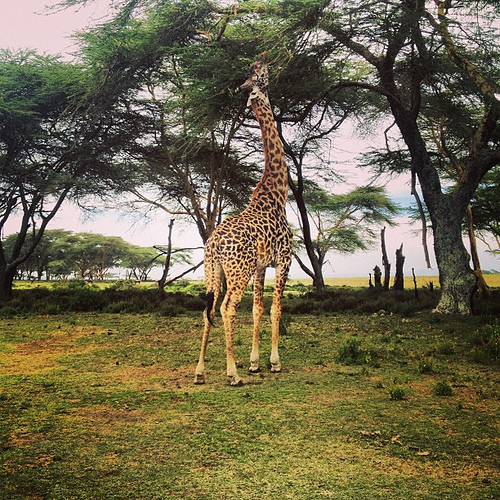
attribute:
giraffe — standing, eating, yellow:
[183, 81, 330, 395]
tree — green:
[4, 50, 147, 310]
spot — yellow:
[256, 228, 277, 242]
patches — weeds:
[335, 334, 380, 374]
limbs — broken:
[300, 64, 399, 130]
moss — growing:
[435, 247, 474, 301]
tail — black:
[193, 264, 227, 334]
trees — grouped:
[269, 30, 492, 315]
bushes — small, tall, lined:
[8, 279, 208, 324]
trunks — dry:
[350, 236, 415, 303]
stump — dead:
[365, 242, 408, 303]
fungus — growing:
[355, 297, 411, 333]